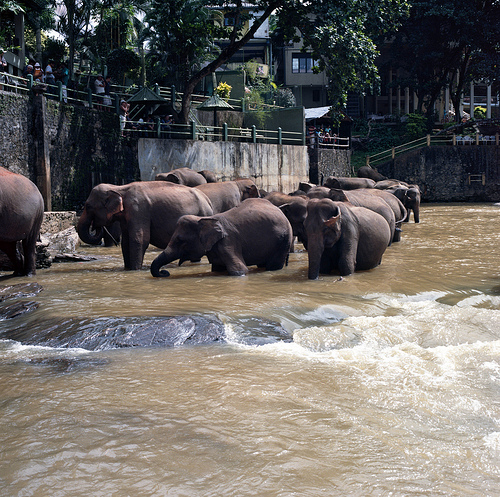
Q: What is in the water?
A: ELEPHANTS.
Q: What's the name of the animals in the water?
A: Elephants.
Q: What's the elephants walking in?
A: Water.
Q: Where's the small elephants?
A: In the water.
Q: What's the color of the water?
A: Brown.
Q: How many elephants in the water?
A: There's a lot.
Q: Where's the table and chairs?
A: In the area above the elephants.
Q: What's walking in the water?
A: Group of elephants.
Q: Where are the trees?
A: Above the elephants.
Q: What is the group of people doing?
A: Watching the group of elephants.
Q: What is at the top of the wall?
A: Wooden fence.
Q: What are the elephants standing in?
A: Water.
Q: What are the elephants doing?
A: Drinking water.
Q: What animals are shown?
A: Elephants.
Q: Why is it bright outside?
A: Its daytime.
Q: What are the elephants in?
A: Water.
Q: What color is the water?
A: Brown.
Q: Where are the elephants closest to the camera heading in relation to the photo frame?
A: Left.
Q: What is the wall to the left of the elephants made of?
A: Stone.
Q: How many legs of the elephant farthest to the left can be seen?
A: Two.